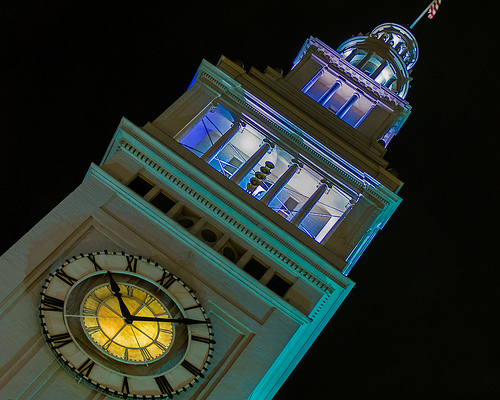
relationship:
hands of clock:
[102, 267, 216, 339] [38, 249, 212, 399]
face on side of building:
[79, 282, 175, 361] [1, 0, 464, 397]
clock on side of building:
[38, 249, 212, 399] [1, 0, 464, 397]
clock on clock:
[38, 249, 212, 399] [38, 249, 212, 399]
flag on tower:
[428, 0, 440, 19] [0, 17, 421, 397]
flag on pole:
[428, 0, 439, 19] [406, 0, 433, 34]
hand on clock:
[97, 262, 142, 317] [38, 249, 212, 399]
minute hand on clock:
[127, 312, 213, 326] [69, 265, 190, 371]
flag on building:
[428, 0, 439, 19] [0, 0, 442, 397]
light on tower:
[341, 90, 369, 128] [226, 12, 430, 336]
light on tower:
[311, 72, 344, 114] [226, 12, 430, 336]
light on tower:
[303, 187, 343, 247] [226, 12, 430, 336]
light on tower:
[246, 147, 296, 204] [226, 12, 430, 336]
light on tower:
[191, 107, 230, 159] [226, 12, 430, 336]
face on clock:
[79, 282, 175, 361] [38, 249, 212, 399]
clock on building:
[38, 249, 212, 399] [0, 0, 442, 397]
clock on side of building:
[31, 230, 240, 399] [1, 0, 464, 397]